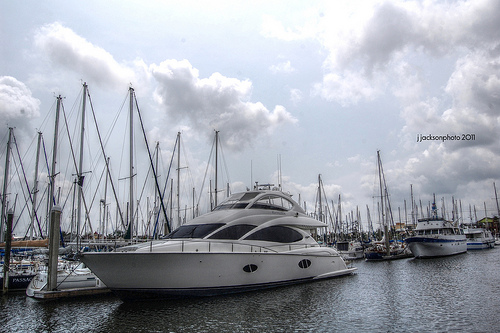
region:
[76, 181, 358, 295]
white luxury speed boat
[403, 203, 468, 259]
white ship with a blue stripe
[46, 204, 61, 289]
post at the end of the dock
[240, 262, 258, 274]
porthole on the side of a white boat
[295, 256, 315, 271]
porthole towards back of boat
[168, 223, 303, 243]
windows on the white luxury boat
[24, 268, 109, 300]
end of the dock near the front of the boat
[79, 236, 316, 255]
railing along the edge of the boat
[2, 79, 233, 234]
group of masts behind the white luxury boat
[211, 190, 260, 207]
small windows on the top level of the boat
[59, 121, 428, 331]
a boat in the water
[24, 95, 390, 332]
a yacht in the water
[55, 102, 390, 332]
a white boat in the water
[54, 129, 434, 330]
a white yacht in the water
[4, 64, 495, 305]
boats in the water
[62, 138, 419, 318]
a small yacht in the water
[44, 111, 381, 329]
a small white boat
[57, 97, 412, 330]
a small white yacht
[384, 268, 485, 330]
a body of water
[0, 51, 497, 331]
a body of water with boats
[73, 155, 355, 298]
a large boat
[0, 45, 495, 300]
boats docked at a harbor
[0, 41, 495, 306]
many boats at a harbor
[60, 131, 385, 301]
a fancy yacht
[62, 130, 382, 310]
a fancy white boat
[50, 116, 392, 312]
a yacht docked at a harbor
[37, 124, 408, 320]
a large white boat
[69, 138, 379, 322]
a sleek boat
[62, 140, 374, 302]
a very sleek yacht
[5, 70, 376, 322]
sailboats and a yacht docked at a harbor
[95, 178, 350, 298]
boat in the water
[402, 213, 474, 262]
boat in the water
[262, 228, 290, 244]
window on side of boat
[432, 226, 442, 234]
window on the boat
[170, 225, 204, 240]
window on the boat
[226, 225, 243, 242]
window on the boat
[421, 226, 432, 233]
window on the boat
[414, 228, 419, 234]
window on the boat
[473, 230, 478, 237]
window on the boat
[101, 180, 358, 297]
ship in the water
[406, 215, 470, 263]
ship in the water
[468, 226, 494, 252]
ship in the water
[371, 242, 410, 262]
ship in the water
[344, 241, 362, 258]
ship in the water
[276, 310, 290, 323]
ripple in the water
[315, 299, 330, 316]
ripple in the water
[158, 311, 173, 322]
ripple in the water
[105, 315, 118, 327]
ripple in the water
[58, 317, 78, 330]
ripple in the water